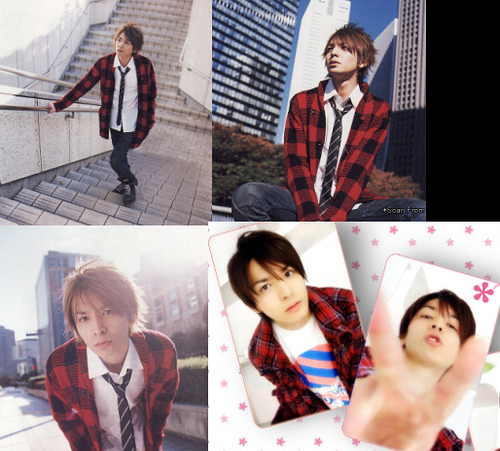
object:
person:
[47, 23, 160, 206]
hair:
[113, 23, 145, 54]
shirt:
[86, 336, 149, 451]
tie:
[116, 64, 129, 128]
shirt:
[283, 80, 393, 222]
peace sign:
[368, 296, 483, 400]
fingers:
[345, 293, 483, 450]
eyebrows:
[79, 308, 120, 323]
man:
[230, 22, 426, 220]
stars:
[349, 226, 492, 304]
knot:
[117, 72, 128, 78]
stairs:
[0, 147, 212, 222]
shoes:
[114, 178, 141, 206]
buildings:
[212, 1, 427, 197]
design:
[295, 342, 340, 392]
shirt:
[272, 318, 349, 410]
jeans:
[228, 181, 427, 221]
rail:
[1, 69, 106, 118]